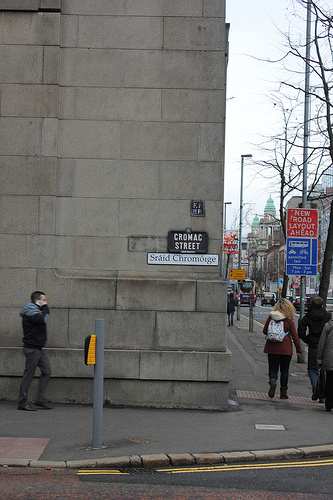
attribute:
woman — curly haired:
[262, 295, 304, 400]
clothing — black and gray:
[18, 298, 61, 413]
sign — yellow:
[228, 267, 247, 281]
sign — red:
[286, 204, 329, 250]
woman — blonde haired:
[243, 269, 297, 420]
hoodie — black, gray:
[19, 302, 49, 349]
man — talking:
[13, 285, 61, 416]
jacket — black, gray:
[19, 298, 53, 353]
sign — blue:
[279, 239, 324, 277]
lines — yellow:
[75, 457, 331, 473]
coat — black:
[297, 307, 330, 348]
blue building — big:
[260, 191, 276, 215]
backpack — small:
[267, 317, 290, 342]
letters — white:
[289, 209, 315, 239]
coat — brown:
[261, 308, 308, 362]